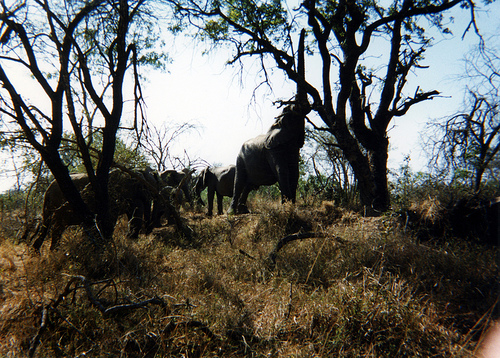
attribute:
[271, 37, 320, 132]
trunk — upwards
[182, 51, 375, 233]
elephant — large, standing, away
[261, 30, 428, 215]
tree — small, large, broken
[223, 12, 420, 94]
branch — bare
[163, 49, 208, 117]
sky — gray, blue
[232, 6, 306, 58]
leaves — green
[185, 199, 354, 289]
grass — tall, green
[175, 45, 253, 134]
sun — out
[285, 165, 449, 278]
underbrush — yellow